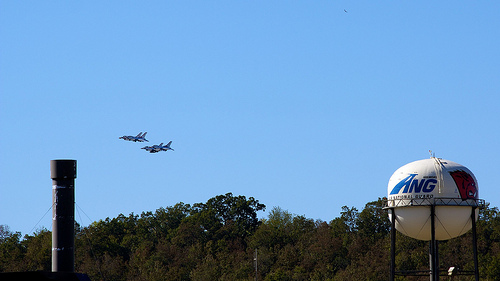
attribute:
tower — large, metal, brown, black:
[47, 160, 88, 278]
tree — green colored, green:
[0, 197, 500, 273]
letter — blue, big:
[383, 172, 415, 199]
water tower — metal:
[382, 150, 487, 280]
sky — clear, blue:
[2, 1, 500, 241]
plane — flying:
[140, 136, 180, 165]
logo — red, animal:
[448, 168, 484, 200]